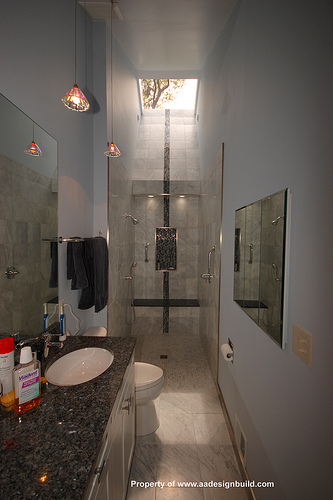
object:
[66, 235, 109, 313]
towel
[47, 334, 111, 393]
sink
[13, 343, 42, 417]
bottle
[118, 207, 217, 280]
shower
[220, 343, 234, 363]
paper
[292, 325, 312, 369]
air vent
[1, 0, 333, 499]
bathroom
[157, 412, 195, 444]
tile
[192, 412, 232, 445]
tile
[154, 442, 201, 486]
tile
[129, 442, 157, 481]
tile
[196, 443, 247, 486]
tile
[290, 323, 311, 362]
light switches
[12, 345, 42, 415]
mouthwash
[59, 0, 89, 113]
lamp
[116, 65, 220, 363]
shower stall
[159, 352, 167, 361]
drain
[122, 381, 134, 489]
cabinet doors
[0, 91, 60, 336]
mirror hanging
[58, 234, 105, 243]
towel rack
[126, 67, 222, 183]
shine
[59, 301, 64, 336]
toothbrush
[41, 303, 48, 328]
toothbrush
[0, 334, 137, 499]
counter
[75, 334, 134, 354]
grey counter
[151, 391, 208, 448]
reflecting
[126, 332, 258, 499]
floor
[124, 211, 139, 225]
shower head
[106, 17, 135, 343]
wall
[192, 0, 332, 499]
wall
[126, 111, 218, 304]
wall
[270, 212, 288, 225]
shower head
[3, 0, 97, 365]
wall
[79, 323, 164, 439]
toilet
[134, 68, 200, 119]
panel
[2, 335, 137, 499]
granite top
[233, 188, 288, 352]
mirror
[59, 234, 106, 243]
rack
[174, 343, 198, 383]
ground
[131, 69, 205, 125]
sky light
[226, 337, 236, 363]
holder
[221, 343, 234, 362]
roll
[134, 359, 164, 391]
toilet seat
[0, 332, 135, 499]
vanity top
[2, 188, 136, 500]
vanity